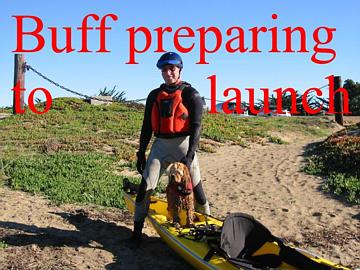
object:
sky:
[0, 0, 360, 73]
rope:
[25, 62, 152, 106]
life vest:
[151, 87, 192, 133]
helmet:
[156, 51, 185, 69]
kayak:
[119, 185, 345, 270]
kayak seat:
[217, 213, 293, 269]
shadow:
[0, 216, 86, 252]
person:
[122, 51, 214, 251]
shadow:
[48, 209, 170, 269]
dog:
[164, 161, 197, 227]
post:
[11, 52, 27, 115]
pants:
[134, 135, 210, 222]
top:
[137, 81, 200, 160]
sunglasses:
[160, 66, 177, 72]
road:
[203, 119, 359, 265]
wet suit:
[129, 84, 214, 228]